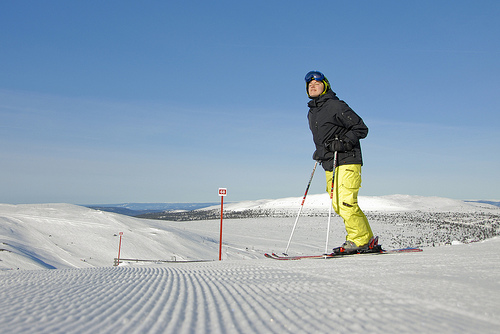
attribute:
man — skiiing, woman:
[298, 67, 385, 258]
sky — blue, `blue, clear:
[3, 2, 499, 207]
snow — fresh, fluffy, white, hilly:
[3, 199, 496, 326]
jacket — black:
[306, 97, 367, 166]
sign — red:
[217, 183, 232, 258]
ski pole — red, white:
[322, 141, 341, 256]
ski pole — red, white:
[279, 148, 322, 254]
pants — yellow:
[330, 163, 373, 248]